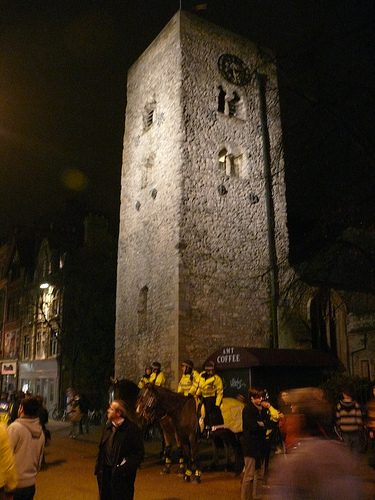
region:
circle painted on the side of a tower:
[214, 48, 256, 91]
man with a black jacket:
[89, 395, 152, 489]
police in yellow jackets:
[104, 355, 259, 476]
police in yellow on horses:
[137, 353, 243, 488]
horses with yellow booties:
[140, 382, 206, 491]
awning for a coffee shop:
[203, 342, 347, 377]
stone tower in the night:
[107, 7, 287, 375]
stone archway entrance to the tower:
[299, 279, 356, 377]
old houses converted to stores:
[5, 232, 102, 394]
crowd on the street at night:
[6, 380, 166, 471]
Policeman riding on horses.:
[179, 358, 226, 439]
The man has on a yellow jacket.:
[194, 373, 233, 395]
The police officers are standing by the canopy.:
[210, 331, 328, 397]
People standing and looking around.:
[82, 397, 148, 488]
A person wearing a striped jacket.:
[320, 398, 367, 438]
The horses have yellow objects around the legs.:
[181, 464, 213, 479]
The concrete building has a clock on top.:
[212, 42, 274, 98]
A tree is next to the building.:
[57, 302, 108, 388]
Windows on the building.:
[16, 293, 65, 357]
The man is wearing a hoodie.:
[2, 401, 56, 485]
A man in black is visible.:
[93, 403, 130, 463]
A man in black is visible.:
[72, 430, 117, 497]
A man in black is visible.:
[68, 408, 105, 489]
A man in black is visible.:
[82, 381, 143, 497]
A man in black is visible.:
[35, 370, 141, 495]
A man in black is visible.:
[118, 393, 156, 495]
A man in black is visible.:
[94, 442, 126, 493]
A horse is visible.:
[131, 385, 243, 481]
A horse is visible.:
[176, 405, 243, 497]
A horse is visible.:
[143, 425, 210, 492]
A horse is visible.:
[124, 349, 284, 495]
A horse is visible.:
[153, 358, 219, 494]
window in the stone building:
[201, 135, 255, 191]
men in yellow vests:
[174, 355, 229, 413]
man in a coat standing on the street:
[86, 392, 145, 498]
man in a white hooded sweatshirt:
[8, 395, 41, 495]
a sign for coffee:
[208, 340, 255, 370]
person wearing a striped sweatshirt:
[333, 383, 363, 444]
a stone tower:
[121, 197, 264, 347]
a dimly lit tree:
[33, 236, 114, 407]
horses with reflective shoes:
[161, 447, 207, 490]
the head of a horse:
[130, 377, 173, 432]